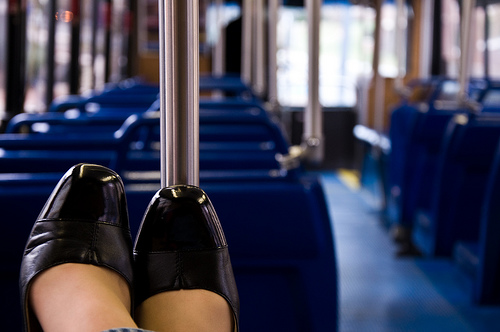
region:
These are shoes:
[52, 192, 165, 329]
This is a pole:
[156, 124, 210, 139]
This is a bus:
[169, 21, 378, 256]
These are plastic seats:
[262, 248, 326, 327]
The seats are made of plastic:
[211, 137, 293, 326]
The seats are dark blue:
[202, 162, 315, 290]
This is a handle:
[207, 96, 292, 181]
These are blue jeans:
[93, 309, 125, 327]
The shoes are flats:
[87, 177, 201, 258]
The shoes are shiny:
[107, 278, 280, 315]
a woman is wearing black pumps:
[19, 147, 235, 314]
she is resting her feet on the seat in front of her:
[26, 143, 306, 324]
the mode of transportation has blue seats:
[215, 75, 341, 289]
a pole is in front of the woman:
[146, 15, 234, 180]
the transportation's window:
[226, 10, 393, 95]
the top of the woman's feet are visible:
[42, 278, 239, 328]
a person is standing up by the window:
[219, 8, 289, 102]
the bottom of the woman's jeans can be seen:
[93, 320, 152, 330]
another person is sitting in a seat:
[368, 60, 460, 255]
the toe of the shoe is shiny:
[38, 140, 238, 247]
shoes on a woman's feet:
[11, 143, 251, 330]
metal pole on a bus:
[133, 14, 225, 179]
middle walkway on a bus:
[334, 182, 435, 315]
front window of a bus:
[326, 23, 363, 97]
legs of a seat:
[388, 224, 432, 269]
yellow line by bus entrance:
[333, 168, 364, 195]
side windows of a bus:
[11, 2, 133, 97]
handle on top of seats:
[200, 100, 292, 174]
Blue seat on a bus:
[14, 97, 266, 139]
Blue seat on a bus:
[378, 96, 477, 220]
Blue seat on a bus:
[427, 106, 496, 303]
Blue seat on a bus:
[9, 159, 319, 244]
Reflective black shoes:
[9, 141, 277, 305]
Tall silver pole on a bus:
[143, 9, 221, 185]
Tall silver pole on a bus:
[290, 19, 327, 171]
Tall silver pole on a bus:
[447, 16, 489, 136]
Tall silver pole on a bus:
[230, 10, 315, 137]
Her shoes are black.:
[15, 167, 252, 305]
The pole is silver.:
[157, 3, 197, 182]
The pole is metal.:
[158, 1, 198, 183]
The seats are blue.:
[45, 70, 355, 329]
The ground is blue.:
[299, 145, 436, 330]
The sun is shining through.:
[279, 7, 363, 106]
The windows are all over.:
[279, 10, 499, 89]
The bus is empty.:
[10, 6, 498, 316]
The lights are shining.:
[60, 157, 210, 206]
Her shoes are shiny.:
[30, 149, 236, 256]